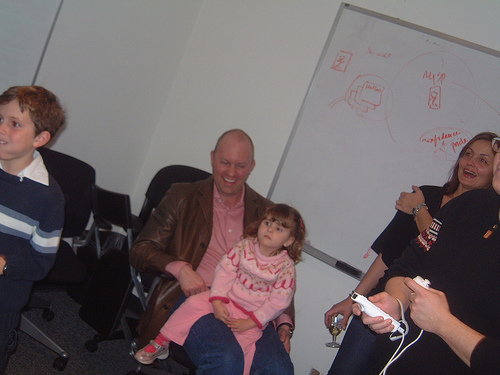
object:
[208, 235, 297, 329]
sweater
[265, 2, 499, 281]
board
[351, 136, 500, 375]
man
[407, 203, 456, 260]
ground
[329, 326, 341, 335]
beverage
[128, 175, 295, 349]
brown jacket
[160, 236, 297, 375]
outfit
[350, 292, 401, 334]
remote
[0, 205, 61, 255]
stripe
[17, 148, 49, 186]
shirt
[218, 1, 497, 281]
wall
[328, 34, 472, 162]
drawings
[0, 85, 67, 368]
boy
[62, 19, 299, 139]
wall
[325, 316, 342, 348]
glass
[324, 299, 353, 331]
hand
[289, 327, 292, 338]
wristwatch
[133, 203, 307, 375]
child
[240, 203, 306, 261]
hair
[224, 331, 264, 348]
lap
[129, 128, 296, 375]
dad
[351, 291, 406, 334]
hand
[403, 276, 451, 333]
hand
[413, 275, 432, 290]
wii controller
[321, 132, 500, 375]
person